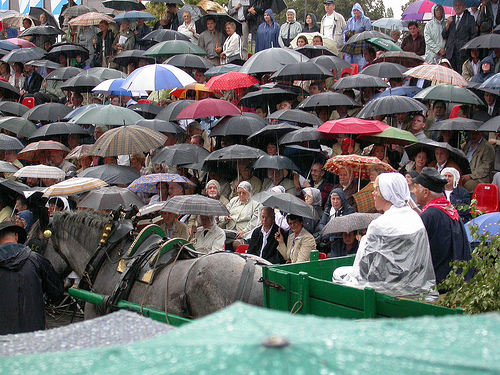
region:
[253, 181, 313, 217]
a black umbrella in hand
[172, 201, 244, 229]
a black umbrella in hand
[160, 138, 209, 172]
a black umbrella in hand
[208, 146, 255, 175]
a black umbrella in hand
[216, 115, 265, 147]
a black umbrella in hand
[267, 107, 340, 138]
a black umbrella in hand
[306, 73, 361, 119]
a black umbrella in hand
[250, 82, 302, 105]
a black umbrella in hand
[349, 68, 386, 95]
a black umbrella in hand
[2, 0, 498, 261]
Large crowd of people, many standing under umbrellas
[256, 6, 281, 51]
Person on hill wearing blue jacket with no umbrella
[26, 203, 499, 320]
Gray horse pulling a bright green wagon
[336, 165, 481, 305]
Man and woman riding in wagon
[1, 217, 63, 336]
Man in black leading gray horse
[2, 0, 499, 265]
Crowd of spectators standing in the rain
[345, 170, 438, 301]
Woman in old-fashioned clothing covered with clear plastic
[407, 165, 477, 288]
Man in old-fashioned black clothing wearing a hat and red bandanna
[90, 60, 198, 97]
Pair of blue and white striped umbrellas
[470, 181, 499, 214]
Vacant red plastic chair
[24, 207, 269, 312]
Grey horse with black leather saddle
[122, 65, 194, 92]
Blue and white umbrella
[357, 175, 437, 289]
Woman in white plastic covering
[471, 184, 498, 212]
Empty red chair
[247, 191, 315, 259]
Elderly couple sharing an umbrella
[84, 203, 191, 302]
Black saddle with gold embellishments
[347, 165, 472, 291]
Elderly couple in horse-drawn carriage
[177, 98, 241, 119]
Red umbrella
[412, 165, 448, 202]
Black cap on elderly man's head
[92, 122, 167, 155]
large plaid umbrella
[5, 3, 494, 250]
spectators at an event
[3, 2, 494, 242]
spectators on a rainy day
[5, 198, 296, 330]
dark grey horse pulling a green wagon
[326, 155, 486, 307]
man and woman riding in green wagon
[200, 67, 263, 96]
red umbrella protecting spectator from rain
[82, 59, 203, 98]
two blue and white umbrellas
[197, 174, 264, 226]
two spectators without umbrellas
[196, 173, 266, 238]
two spectators with rain ponchos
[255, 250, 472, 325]
green horse drawn wagon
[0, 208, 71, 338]
man leading horse wearing a black poncho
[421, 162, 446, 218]
This man is wearing a black hat here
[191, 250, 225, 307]
This horse has a rather gray body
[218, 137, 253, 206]
There is a black umbrella in the middle of the crowd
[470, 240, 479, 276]
There are some green leaves here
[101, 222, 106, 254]
There are some gold decorations on the horse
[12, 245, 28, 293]
This man has a rather dark rain coat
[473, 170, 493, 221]
There is a red chair that is visible here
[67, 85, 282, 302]
This photo has very vibrant colors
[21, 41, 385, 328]
A group of people with umbrellas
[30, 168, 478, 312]
A man and woman in a horse and buggy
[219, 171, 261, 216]
A woman with a rain hat on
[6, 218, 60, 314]
A man in a black jacket next to the horse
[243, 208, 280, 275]
A man in a white shirt looking at the buggy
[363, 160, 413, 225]
A woman with a white hat on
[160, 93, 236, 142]
A membrane umbrella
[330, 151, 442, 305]
woman sitting in trailer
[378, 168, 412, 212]
woman wearing plastic cap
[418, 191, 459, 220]
man wearing neckerchief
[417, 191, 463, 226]
man's scarf is red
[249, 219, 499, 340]
trailer behind horse is green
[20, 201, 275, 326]
horse pulling green trailer